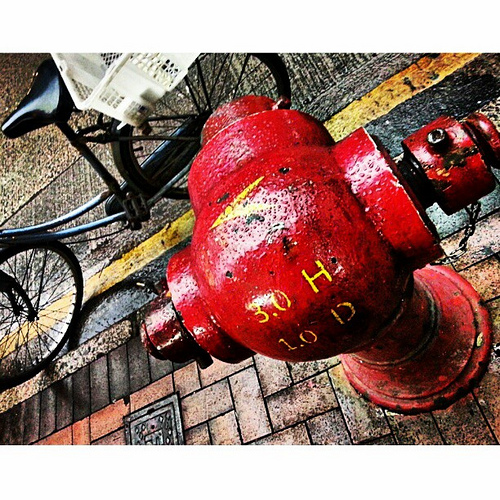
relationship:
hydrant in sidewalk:
[120, 119, 495, 409] [10, 224, 496, 453]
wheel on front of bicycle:
[1, 245, 83, 387] [2, 54, 290, 379]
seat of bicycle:
[5, 62, 71, 136] [2, 54, 290, 379]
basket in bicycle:
[47, 56, 201, 118] [2, 54, 290, 379]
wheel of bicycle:
[106, 47, 316, 199] [2, 54, 290, 379]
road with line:
[3, 58, 495, 359] [2, 58, 490, 313]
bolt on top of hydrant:
[427, 129, 449, 147] [120, 119, 495, 409]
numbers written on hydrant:
[245, 266, 358, 347] [120, 119, 495, 409]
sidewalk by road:
[10, 224, 496, 453] [3, 58, 495, 359]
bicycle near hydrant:
[2, 54, 290, 379] [120, 119, 495, 409]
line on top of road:
[2, 58, 490, 313] [3, 58, 495, 359]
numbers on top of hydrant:
[245, 266, 358, 347] [120, 119, 495, 409]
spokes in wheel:
[153, 54, 271, 112] [106, 47, 316, 199]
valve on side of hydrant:
[131, 300, 205, 369] [120, 119, 495, 409]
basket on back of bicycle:
[47, 56, 201, 118] [2, 54, 290, 379]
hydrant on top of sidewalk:
[120, 119, 495, 409] [10, 224, 496, 453]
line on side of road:
[2, 58, 490, 313] [3, 58, 495, 359]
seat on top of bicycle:
[5, 62, 71, 136] [2, 54, 290, 379]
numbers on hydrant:
[245, 266, 358, 347] [120, 119, 495, 409]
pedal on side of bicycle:
[125, 195, 143, 227] [2, 54, 290, 379]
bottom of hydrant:
[346, 265, 495, 412] [120, 119, 495, 409]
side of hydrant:
[335, 129, 496, 258] [120, 119, 495, 409]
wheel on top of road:
[1, 245, 83, 387] [3, 58, 495, 359]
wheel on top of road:
[106, 47, 316, 199] [3, 58, 495, 359]